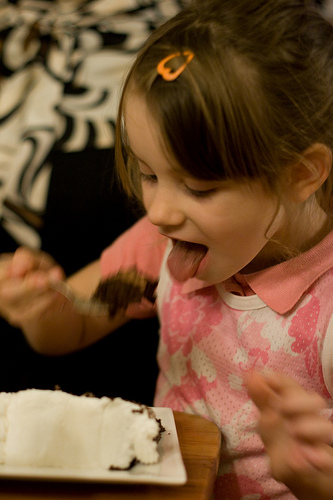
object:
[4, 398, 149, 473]
slice of cake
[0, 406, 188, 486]
plate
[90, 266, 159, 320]
piece of cake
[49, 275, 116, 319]
fork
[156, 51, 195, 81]
barrett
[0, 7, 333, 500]
girl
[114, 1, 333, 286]
hair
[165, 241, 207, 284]
tongue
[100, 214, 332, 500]
dress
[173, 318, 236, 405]
patterns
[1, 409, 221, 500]
table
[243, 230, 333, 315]
collar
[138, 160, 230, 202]
eyes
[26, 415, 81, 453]
icing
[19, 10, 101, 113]
patterns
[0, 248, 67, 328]
hand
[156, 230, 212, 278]
mouth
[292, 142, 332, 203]
ear